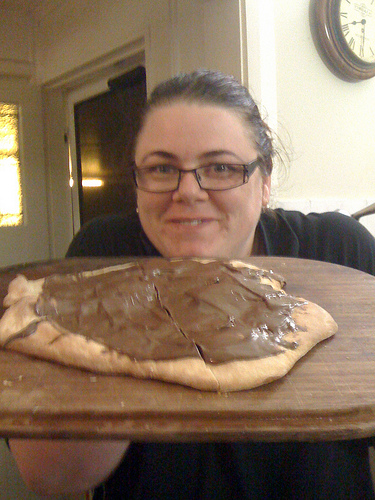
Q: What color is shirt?
A: Black.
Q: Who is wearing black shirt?
A: The woman.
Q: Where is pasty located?
A: On board.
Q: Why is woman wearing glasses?
A: To see.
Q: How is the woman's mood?
A: Happy.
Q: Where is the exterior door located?
A: Rear left.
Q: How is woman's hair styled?
A: Pulled into bun.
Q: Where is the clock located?
A: Upper right.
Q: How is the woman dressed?
A: Black polo.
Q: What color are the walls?
A: White.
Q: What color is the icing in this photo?
A: Brown.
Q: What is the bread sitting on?
A: A cutting board.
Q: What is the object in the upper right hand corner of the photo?
A: A clock.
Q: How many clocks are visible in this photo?
A: One.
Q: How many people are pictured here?
A: One.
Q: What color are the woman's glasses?
A: Black.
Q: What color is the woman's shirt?
A: Black.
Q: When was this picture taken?
A: 8:30.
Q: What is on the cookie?
A: Chocolate icing.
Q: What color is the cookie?
A: Tan.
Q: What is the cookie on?
A: Cutting board.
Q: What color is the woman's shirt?
A: Black.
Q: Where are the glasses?
A: Woman's face.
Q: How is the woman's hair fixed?
A: Pulled back.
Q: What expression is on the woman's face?
A: Smile.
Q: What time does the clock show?
A: 8:30.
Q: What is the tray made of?
A: Wood.